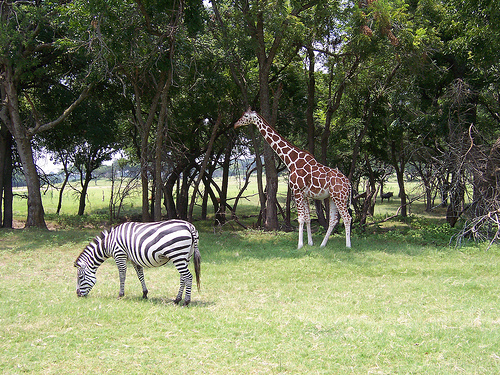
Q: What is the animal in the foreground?
A: A zebra.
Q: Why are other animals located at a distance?
A: Wildlife preserve.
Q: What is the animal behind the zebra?
A: A giraffe.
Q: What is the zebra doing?
A: Grazing.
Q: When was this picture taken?
A: Daytime.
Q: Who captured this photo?
A: A photographer.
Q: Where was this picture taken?
A: At an open zoo.